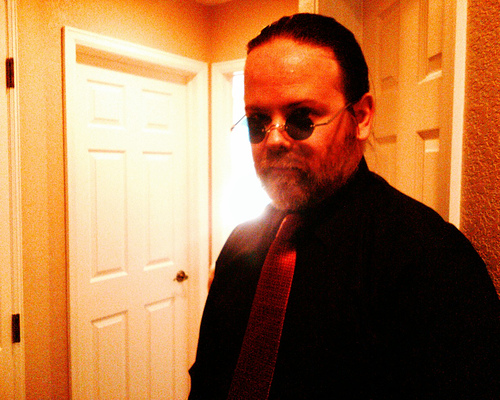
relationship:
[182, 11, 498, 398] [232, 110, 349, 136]
man has black sunglasses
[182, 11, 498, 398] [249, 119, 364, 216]
man has beard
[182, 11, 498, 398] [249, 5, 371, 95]
man has hair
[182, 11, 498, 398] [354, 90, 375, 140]
man has ear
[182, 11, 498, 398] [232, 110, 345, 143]
man wears sunglasses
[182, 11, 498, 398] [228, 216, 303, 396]
man wears tie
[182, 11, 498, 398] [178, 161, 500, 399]
man wears dress shirt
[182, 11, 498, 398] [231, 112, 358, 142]
man wears sunglasses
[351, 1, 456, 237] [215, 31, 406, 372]
door behind man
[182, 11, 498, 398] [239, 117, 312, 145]
man wears black sunglasses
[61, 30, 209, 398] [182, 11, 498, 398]
door left of man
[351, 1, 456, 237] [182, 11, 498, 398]
door behind man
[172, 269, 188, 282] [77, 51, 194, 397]
handle on door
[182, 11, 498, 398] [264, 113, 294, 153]
man has nose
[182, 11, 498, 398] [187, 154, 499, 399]
man wears shirt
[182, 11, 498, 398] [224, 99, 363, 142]
man wears sunglasses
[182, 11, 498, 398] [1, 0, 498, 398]
man standing in hallway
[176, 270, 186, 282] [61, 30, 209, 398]
handle on a door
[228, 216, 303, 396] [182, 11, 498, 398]
tie on a man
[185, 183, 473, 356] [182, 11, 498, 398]
dress shirt on a man